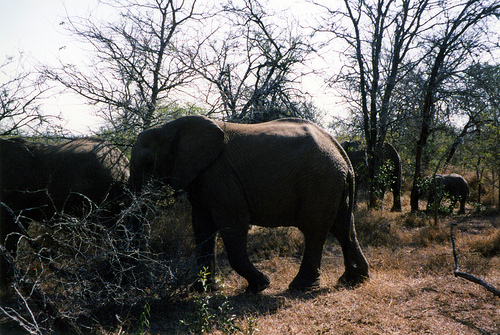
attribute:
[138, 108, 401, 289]
elephant — here, standing, black, grey, huge, giant, massive, bent, large, looking, walking, below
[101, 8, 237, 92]
tree — bare, dying, dead , skinny, close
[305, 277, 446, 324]
ground — brown, below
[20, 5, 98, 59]
sky — above, high, here, overcast, white, blue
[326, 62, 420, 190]
plant — small , green 